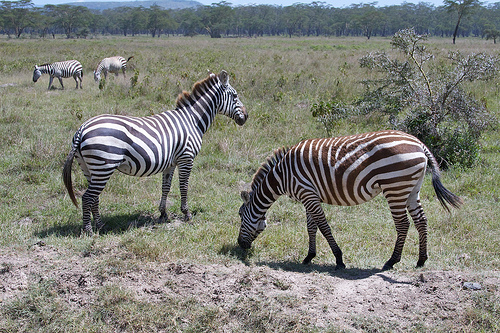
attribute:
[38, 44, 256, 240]
zebra — male, looking, searching, watching, out, having, enjoying, eating, head, tail, stripped, walking, four, striped, standing, grazing, black, swinging, hoove, eye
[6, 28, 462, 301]
scenery — safari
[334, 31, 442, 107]
dirt — mount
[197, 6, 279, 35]
tree — distance